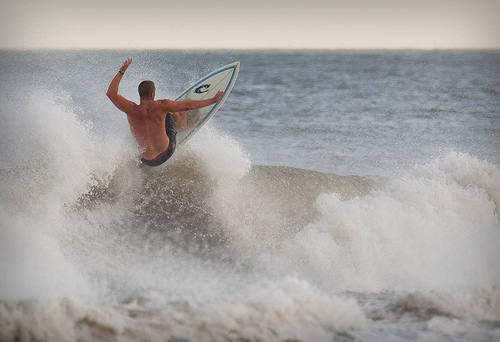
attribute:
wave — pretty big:
[330, 98, 448, 144]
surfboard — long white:
[164, 61, 244, 156]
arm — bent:
[106, 59, 136, 111]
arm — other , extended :
[106, 55, 220, 124]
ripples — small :
[297, 59, 428, 141]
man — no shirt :
[97, 46, 240, 176]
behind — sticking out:
[138, 136, 171, 167]